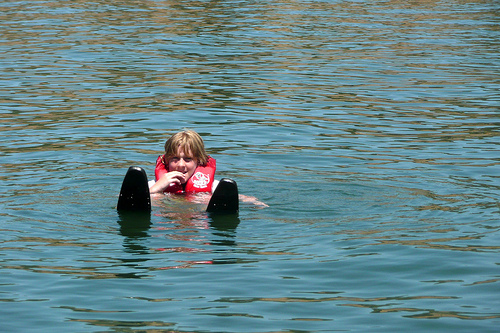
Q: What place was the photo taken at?
A: It was taken at the lake.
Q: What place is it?
A: It is a lake.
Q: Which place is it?
A: It is a lake.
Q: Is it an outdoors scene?
A: Yes, it is outdoors.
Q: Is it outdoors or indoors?
A: It is outdoors.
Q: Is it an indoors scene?
A: No, it is outdoors.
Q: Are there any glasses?
A: No, there are no glasses.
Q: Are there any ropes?
A: No, there are no ropes.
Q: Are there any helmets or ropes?
A: No, there are no ropes or helmets.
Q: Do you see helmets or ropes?
A: No, there are no ropes or helmets.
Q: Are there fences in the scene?
A: No, there are no fences.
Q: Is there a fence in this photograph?
A: No, there are no fences.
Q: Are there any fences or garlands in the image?
A: No, there are no fences or garlands.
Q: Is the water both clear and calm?
A: Yes, the water is clear and calm.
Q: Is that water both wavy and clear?
A: No, the water is clear but calm.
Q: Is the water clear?
A: Yes, the water is clear.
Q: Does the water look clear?
A: Yes, the water is clear.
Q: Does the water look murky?
A: No, the water is clear.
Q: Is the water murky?
A: No, the water is clear.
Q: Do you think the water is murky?
A: No, the water is clear.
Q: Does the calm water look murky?
A: No, the water is clear.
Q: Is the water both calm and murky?
A: No, the water is calm but clear.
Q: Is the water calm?
A: Yes, the water is calm.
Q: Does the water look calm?
A: Yes, the water is calm.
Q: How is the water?
A: The water is calm.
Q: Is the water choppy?
A: No, the water is calm.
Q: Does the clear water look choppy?
A: No, the water is calm.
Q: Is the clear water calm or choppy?
A: The water is calm.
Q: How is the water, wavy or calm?
A: The water is calm.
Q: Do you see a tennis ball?
A: No, there are no tennis balls.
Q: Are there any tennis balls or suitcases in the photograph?
A: No, there are no tennis balls or suitcases.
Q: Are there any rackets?
A: No, there are no rackets.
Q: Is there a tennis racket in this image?
A: No, there are no rackets.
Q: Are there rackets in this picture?
A: No, there are no rackets.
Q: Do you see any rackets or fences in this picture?
A: No, there are no rackets or fences.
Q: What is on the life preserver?
A: The logo is on the life preserver.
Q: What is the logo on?
A: The logo is on the life preserver.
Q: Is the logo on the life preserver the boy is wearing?
A: Yes, the logo is on the life preserver.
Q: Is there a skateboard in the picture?
A: No, there are no skateboards.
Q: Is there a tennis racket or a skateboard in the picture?
A: No, there are no skateboards or rackets.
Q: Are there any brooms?
A: No, there are no brooms.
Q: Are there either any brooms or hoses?
A: No, there are no brooms or hoses.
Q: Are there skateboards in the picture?
A: No, there are no skateboards.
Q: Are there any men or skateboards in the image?
A: No, there are no skateboards or men.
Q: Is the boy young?
A: Yes, the boy is young.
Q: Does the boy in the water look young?
A: Yes, the boy is young.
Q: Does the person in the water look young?
A: Yes, the boy is young.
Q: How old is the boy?
A: The boy is young.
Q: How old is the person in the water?
A: The boy is young.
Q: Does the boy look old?
A: No, the boy is young.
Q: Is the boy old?
A: No, the boy is young.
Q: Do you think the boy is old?
A: No, the boy is young.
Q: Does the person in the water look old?
A: No, the boy is young.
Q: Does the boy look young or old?
A: The boy is young.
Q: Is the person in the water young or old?
A: The boy is young.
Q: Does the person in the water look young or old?
A: The boy is young.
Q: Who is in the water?
A: The boy is in the water.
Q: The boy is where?
A: The boy is in the water.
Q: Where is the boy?
A: The boy is in the water.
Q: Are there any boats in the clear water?
A: No, there is a boy in the water.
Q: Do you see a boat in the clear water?
A: No, there is a boy in the water.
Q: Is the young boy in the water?
A: Yes, the boy is in the water.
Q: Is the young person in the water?
A: Yes, the boy is in the water.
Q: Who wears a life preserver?
A: The boy wears a life preserver.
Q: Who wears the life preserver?
A: The boy wears a life preserver.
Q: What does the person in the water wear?
A: The boy wears a life preserver.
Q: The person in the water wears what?
A: The boy wears a life preserver.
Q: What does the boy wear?
A: The boy wears a life preserver.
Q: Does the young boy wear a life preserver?
A: Yes, the boy wears a life preserver.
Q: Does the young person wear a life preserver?
A: Yes, the boy wears a life preserver.